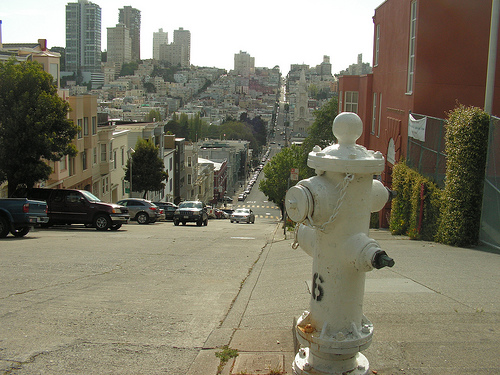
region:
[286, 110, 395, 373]
white fire hydrant with chain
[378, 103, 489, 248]
sculpted green and brown shrubbery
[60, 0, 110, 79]
white skyscraper on skyline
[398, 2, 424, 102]
windows on red building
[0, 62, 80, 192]
large green tree on hill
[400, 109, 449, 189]
green fence with white sign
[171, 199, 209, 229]
black SUV traveling uphill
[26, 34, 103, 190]
tan building with red chimney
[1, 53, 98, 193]
green tree in front of tan building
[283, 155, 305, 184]
red and white traffic sign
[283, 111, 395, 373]
A white fire hydrant.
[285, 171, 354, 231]
A white chain is connected to the cap.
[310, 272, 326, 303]
The number 6 is stenciled on the fire hydrant.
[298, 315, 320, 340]
One bolt is beginning to rust.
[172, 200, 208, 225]
A black SUV is on the street.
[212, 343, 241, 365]
Moss is growing in a crack of the sidewalk.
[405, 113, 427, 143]
A banner is hanging on a fence.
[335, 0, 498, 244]
A brownish red brick building.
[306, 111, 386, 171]
The fire hydrant has a spherical top.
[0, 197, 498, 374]
The street slopes sharply downward.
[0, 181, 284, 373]
view down a city street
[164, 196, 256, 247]
vehicles driving uphill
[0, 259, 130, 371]
cracks on surface of the road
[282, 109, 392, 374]
a white fire hydrant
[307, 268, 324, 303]
number painted on fire hydrant in black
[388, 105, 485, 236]
hedge to the side of and beneath a fence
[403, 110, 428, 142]
slightly sagging banner on fence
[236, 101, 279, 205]
long line of cars parked on left side of street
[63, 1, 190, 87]
skyscrapers in the distance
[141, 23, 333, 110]
buildings on rising hill in the distance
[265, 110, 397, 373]
this is a fire hydrant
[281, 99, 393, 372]
the fire hydrant is white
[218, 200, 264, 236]
this is a car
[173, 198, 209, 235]
this is a car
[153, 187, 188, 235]
this is a car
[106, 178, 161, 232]
this is a car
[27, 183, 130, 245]
this is a car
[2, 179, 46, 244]
this is a car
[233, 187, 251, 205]
this is a car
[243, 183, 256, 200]
this is a car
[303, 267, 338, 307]
6 on the fire hydrant.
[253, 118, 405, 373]
The fire hydrant is white.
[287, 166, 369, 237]
Chain on the hydrant.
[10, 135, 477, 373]
The road is sloped.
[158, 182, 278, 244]
Cars on the road.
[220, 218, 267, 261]
A manhole on the road.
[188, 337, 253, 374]
Small grass patch on the side.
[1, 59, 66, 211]
The tree is green.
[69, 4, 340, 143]
Buildings in the distance.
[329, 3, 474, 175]
The building is reddish brown.